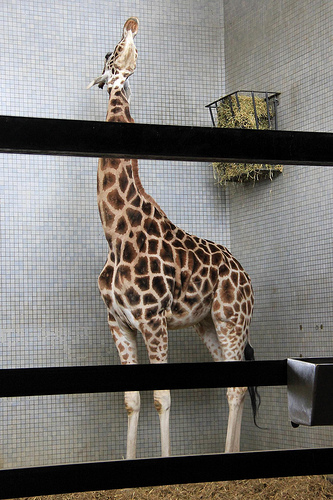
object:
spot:
[142, 293, 156, 303]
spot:
[210, 312, 226, 327]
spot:
[186, 250, 203, 272]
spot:
[149, 353, 160, 361]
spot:
[118, 166, 127, 193]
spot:
[146, 239, 157, 252]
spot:
[122, 241, 137, 262]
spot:
[160, 240, 173, 262]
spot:
[143, 217, 161, 237]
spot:
[220, 279, 235, 301]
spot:
[112, 200, 146, 230]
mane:
[133, 157, 170, 224]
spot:
[224, 306, 233, 318]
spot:
[134, 276, 150, 290]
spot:
[217, 263, 229, 276]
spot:
[144, 325, 154, 341]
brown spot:
[122, 354, 127, 360]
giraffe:
[87, 17, 269, 459]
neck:
[95, 81, 145, 231]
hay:
[0, 444, 332, 496]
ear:
[88, 75, 108, 90]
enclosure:
[1, 112, 332, 499]